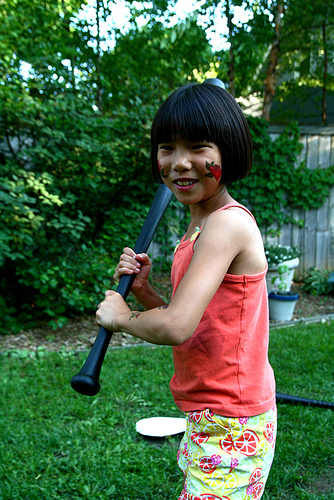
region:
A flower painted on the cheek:
[200, 158, 224, 181]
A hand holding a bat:
[66, 282, 129, 404]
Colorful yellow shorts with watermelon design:
[176, 415, 280, 498]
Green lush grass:
[26, 417, 108, 487]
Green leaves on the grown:
[4, 340, 78, 363]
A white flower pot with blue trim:
[268, 289, 298, 323]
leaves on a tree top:
[33, 117, 134, 174]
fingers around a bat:
[110, 244, 159, 288]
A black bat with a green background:
[133, 199, 175, 239]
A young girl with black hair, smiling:
[144, 79, 257, 206]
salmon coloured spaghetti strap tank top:
[150, 200, 286, 411]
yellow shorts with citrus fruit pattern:
[167, 398, 274, 498]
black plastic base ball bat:
[70, 71, 231, 397]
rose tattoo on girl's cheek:
[199, 159, 225, 184]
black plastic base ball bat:
[270, 388, 332, 410]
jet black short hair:
[139, 78, 253, 189]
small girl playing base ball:
[47, 73, 279, 499]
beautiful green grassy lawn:
[0, 317, 333, 498]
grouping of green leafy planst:
[1, 3, 332, 307]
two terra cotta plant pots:
[260, 240, 308, 327]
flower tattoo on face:
[205, 161, 224, 182]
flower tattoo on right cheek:
[158, 157, 169, 180]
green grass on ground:
[2, 402, 134, 495]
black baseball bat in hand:
[69, 177, 175, 403]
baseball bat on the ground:
[276, 388, 328, 407]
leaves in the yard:
[258, 133, 299, 226]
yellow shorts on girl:
[180, 412, 274, 497]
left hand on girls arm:
[93, 284, 125, 335]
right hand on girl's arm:
[114, 242, 157, 286]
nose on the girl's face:
[173, 153, 192, 173]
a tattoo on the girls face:
[203, 154, 230, 192]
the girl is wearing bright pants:
[146, 375, 281, 499]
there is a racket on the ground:
[122, 395, 193, 446]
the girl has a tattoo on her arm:
[115, 296, 155, 347]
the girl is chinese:
[108, 74, 270, 205]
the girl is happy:
[131, 64, 255, 212]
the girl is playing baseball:
[47, 72, 276, 303]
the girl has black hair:
[123, 52, 259, 205]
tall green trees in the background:
[13, 17, 130, 179]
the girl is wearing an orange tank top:
[127, 69, 275, 324]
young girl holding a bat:
[96, 83, 277, 499]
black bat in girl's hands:
[70, 77, 225, 395]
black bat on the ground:
[276, 392, 333, 407]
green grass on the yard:
[0, 318, 333, 497]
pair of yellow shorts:
[176, 405, 276, 498]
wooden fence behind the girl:
[145, 114, 332, 281]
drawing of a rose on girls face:
[203, 160, 221, 181]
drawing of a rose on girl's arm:
[128, 310, 140, 319]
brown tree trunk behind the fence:
[260, 35, 285, 123]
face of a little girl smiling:
[149, 83, 253, 204]